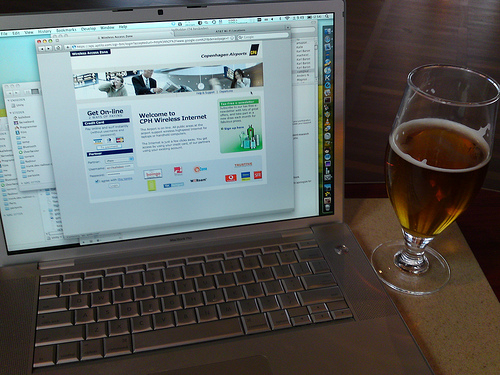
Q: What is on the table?
A: A beer.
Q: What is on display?
A: A news article.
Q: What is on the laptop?
A: The keyboard.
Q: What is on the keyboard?
A: The space bar.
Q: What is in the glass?
A: The beer.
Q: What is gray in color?
A: Laptop.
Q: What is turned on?
A: Laptop.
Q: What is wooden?
A: Desk.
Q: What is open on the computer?
A: Several web pages.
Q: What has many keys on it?
A: The laptop.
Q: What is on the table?
A: A laptop and glass.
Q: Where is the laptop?
A: On a table.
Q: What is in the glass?
A: Beer.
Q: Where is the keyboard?
A: On the laptop.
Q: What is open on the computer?
A: The web.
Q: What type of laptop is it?
A: Mac.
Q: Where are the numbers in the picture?
A: The top of the keyboard.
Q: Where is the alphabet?
A: On the keyboard.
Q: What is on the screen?
A: How to get on the web.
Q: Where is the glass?
A: On the right side of the computer.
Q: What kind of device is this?
A: A laptop.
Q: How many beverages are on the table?
A: One.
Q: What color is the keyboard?
A: Silver.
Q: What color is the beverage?
A: Brown.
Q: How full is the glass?
A: Half.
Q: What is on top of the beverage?
A: Foam.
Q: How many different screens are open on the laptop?
A: Four.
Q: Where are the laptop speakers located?
A: On the sides of the keyboard.